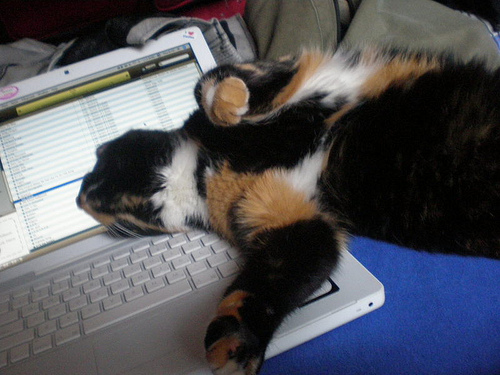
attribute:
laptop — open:
[0, 25, 386, 373]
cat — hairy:
[75, 43, 499, 375]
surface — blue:
[267, 229, 496, 374]